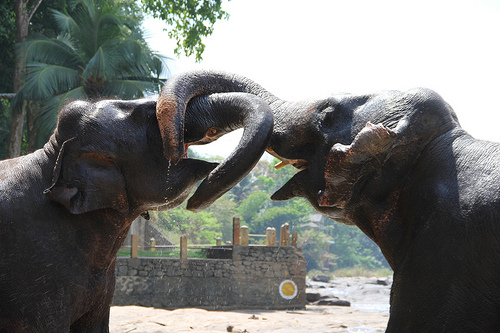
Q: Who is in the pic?
A: Elephants.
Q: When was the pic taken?
A: During the day.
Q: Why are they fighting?
A: They are angry.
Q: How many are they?
A: 2.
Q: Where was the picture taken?
A: A zoo.